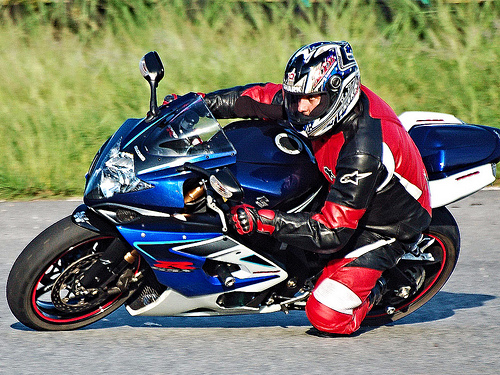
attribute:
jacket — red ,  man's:
[219, 69, 466, 277]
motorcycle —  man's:
[30, 48, 497, 364]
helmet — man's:
[281, 37, 363, 136]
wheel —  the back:
[350, 200, 467, 316]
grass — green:
[23, 33, 82, 111]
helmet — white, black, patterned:
[283, 34, 365, 139]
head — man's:
[277, 33, 397, 145]